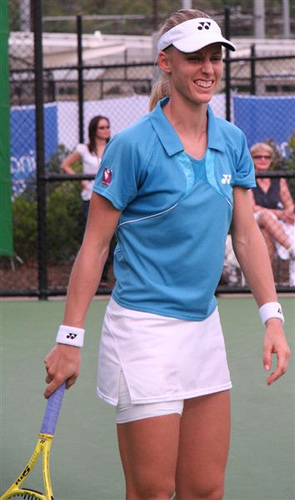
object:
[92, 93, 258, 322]
shirt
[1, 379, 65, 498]
tennis racket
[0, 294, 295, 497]
tennis court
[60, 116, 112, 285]
person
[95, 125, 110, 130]
sunglasses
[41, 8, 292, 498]
woman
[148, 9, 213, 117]
hair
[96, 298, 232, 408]
skirt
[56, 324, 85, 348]
wrist guard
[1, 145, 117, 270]
bush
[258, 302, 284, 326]
wrist guard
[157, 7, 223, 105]
head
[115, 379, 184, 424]
shorts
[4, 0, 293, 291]
fence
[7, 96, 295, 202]
banner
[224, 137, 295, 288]
spectator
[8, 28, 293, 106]
building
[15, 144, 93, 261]
trees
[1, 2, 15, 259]
tarp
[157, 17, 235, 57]
cap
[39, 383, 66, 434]
grip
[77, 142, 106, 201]
white shirt